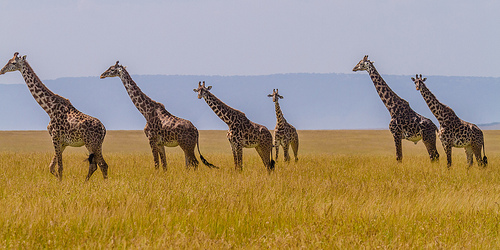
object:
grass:
[0, 129, 500, 249]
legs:
[395, 132, 405, 164]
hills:
[0, 72, 500, 132]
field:
[0, 128, 500, 248]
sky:
[0, 1, 500, 84]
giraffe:
[98, 60, 219, 172]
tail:
[479, 131, 487, 168]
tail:
[266, 137, 276, 175]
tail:
[191, 130, 220, 170]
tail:
[86, 129, 104, 165]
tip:
[480, 155, 487, 166]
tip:
[267, 158, 276, 170]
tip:
[197, 154, 219, 171]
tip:
[82, 153, 98, 166]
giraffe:
[192, 81, 276, 175]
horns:
[197, 81, 201, 88]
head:
[192, 80, 212, 99]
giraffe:
[410, 73, 486, 170]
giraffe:
[353, 54, 441, 163]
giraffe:
[266, 89, 298, 164]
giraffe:
[0, 51, 112, 181]